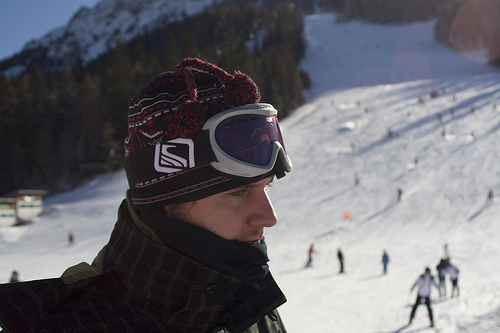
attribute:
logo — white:
[150, 135, 192, 179]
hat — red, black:
[120, 57, 292, 205]